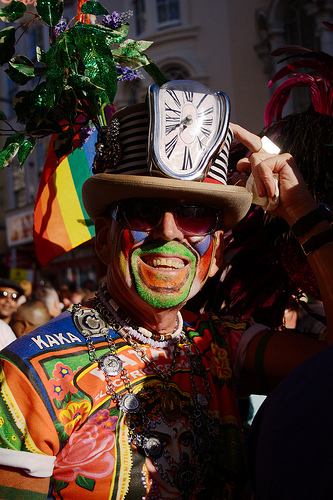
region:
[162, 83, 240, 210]
Black and white clock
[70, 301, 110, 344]
Silver bottlecap on a chain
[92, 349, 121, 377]
Silver bottlecap on a chain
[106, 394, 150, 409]
Silver bottlecap on a chain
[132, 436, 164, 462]
Silver bottlecap on a chain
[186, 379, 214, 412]
Silver bottlecap on a chain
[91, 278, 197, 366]
Necklace around the neck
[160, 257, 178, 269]
Yellow stained teeth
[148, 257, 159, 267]
Yellow stained teeth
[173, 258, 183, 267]
Yellow stained teeth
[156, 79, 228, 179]
man wearing clock hat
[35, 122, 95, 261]
rainbow flag behind man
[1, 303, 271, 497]
man wearing short sleeved shirt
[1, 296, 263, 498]
man wearing colorful shirt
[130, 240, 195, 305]
man with green beard and mustache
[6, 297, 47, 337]
tan man is bald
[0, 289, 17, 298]
man is wearing dark sunglasses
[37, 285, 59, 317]
person has white hair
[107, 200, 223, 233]
man wearing rose colored sunglasses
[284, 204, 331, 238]
man wearing brown bracelet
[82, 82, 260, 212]
melting clock on striped tophat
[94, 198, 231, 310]
garishly painted face with sunglasses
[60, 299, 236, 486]
necklace with multiple silver medallions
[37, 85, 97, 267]
rainbow flag in background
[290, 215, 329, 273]
watch on man's wrist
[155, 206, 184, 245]
unpainted nose in the middle of painted face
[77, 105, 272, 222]
black and white striped tophat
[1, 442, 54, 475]
rolled up sleeve on brightly colored shirt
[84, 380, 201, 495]
image of woman on tshirt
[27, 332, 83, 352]
white letters on blue background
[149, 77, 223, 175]
A crazy shaped clock on a man's head.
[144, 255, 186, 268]
Yellow teeth of a man with paint all over his face.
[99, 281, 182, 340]
White, brown and black necklace on a man's neck.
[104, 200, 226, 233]
Dark sunglasses on a man's face who is wearing a clock.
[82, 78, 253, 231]
A brown hat with a large weird clock on top.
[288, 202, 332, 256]
Two black strap watches on the left wrist of a man.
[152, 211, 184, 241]
A large nose on a man's painted face wearing glasses.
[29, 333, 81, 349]
White word KAKA on a man's shoulder.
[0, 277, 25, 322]
A man's head in the background wearing black glasses and a dark hat.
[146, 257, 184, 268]
Yellow top teeth of a man.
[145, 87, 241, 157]
Clock on the hat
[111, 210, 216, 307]
Man with make up on his face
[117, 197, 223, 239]
Man wearing sunglasses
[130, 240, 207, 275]
Man with a big smile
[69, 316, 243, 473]
Man with a necklace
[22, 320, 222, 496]
Man wearing a multi color shirt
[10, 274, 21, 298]
man wearing a black hat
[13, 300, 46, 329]
Man with a bald head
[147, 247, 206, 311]
Green paint on the face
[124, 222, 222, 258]
Man with blue paint on his face